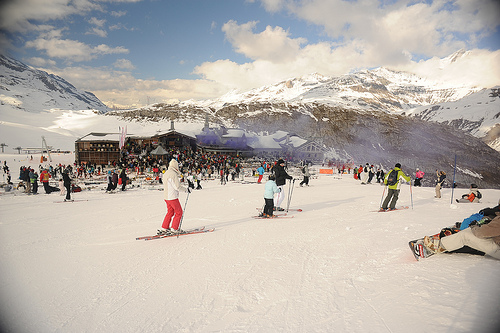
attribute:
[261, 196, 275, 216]
pants — black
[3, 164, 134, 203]
people — group, awaiting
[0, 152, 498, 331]
ground — covered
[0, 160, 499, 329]
snow — white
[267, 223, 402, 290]
snow — white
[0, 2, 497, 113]
sky — blue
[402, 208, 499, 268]
skateboarder — resting, sitting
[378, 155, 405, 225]
skateboarder — resting, sitting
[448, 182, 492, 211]
skateboarder — resting, sitting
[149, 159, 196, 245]
skateboarder — resting, sitting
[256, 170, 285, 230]
skateboarder — resting, sitting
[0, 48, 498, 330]
snow — white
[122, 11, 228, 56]
sky — blue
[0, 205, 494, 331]
snow — white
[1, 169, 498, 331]
slope — snowy 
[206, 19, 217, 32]
cloud — white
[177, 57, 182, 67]
cloud — white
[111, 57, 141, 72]
cloud — white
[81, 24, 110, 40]
cloud — white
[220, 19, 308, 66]
cloud — white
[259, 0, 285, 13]
cloud — white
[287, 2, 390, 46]
cloud — white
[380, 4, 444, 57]
cloud — white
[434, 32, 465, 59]
cloud — white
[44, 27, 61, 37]
cloud — white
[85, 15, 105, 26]
cloud — white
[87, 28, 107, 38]
cloud — white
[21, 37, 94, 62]
cloud — white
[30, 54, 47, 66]
cloud — white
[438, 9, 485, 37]
cloud — white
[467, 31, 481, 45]
cloud — white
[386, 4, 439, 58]
cloud — white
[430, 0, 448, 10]
cloud — white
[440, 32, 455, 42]
cloud — white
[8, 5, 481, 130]
sky — blue